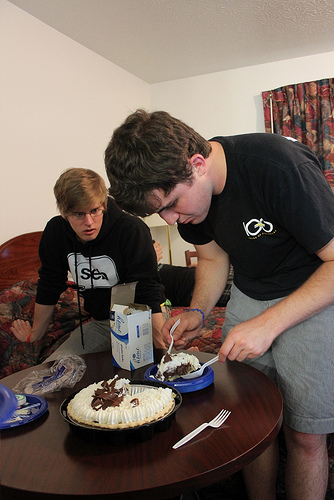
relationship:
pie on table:
[51, 376, 186, 445] [4, 336, 295, 498]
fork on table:
[168, 402, 233, 456] [4, 336, 295, 498]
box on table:
[106, 278, 154, 371] [4, 336, 295, 498]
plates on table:
[154, 351, 220, 395] [4, 336, 295, 498]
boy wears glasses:
[41, 159, 129, 314] [66, 206, 110, 224]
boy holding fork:
[103, 100, 331, 499] [183, 346, 232, 399]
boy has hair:
[103, 100, 331, 499] [123, 130, 187, 170]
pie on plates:
[150, 342, 218, 378] [154, 351, 220, 395]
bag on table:
[11, 351, 86, 397] [4, 336, 295, 498]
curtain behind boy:
[265, 77, 333, 124] [103, 100, 331, 499]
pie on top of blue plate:
[57, 381, 191, 429] [142, 356, 213, 394]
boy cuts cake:
[100, 75, 331, 492] [69, 374, 203, 453]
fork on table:
[171, 407, 233, 449] [4, 336, 295, 498]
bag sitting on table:
[7, 340, 90, 407] [4, 336, 295, 498]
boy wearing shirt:
[103, 100, 331, 499] [178, 134, 324, 302]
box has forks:
[106, 278, 154, 371] [159, 310, 231, 390]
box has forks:
[106, 278, 154, 371] [150, 394, 238, 453]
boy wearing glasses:
[9, 168, 172, 368] [70, 205, 101, 219]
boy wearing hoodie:
[9, 168, 172, 368] [34, 197, 154, 323]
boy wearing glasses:
[9, 168, 172, 368] [67, 207, 109, 219]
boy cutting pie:
[103, 100, 331, 499] [69, 374, 175, 428]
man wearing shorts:
[134, 138, 329, 401] [213, 295, 321, 422]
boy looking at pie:
[41, 159, 129, 314] [110, 336, 215, 412]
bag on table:
[11, 351, 86, 397] [0, 321, 276, 498]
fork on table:
[171, 407, 233, 449] [179, 384, 270, 453]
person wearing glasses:
[9, 166, 178, 367] [67, 207, 105, 217]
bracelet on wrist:
[181, 308, 208, 322] [180, 303, 208, 324]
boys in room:
[35, 110, 333, 374] [32, 138, 330, 454]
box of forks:
[106, 278, 154, 371] [177, 403, 240, 462]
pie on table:
[59, 376, 183, 430] [35, 304, 288, 492]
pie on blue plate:
[162, 341, 202, 384] [142, 356, 213, 394]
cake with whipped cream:
[69, 374, 177, 432] [80, 378, 155, 417]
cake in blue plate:
[69, 374, 177, 432] [142, 356, 213, 394]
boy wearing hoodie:
[41, 159, 129, 314] [34, 197, 166, 326]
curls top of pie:
[93, 380, 136, 412] [80, 367, 163, 424]